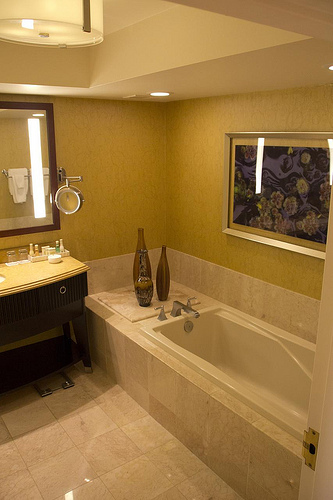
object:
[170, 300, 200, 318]
faucet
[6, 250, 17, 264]
glasses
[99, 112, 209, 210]
wall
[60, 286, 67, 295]
handle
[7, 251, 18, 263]
glass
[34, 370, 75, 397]
scale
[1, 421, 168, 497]
floor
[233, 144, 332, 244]
artwork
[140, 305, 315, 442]
bathtub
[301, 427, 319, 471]
striking plate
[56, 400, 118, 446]
tile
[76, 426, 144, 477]
tile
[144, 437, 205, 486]
tile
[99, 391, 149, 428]
tile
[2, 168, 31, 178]
rack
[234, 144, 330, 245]
flowered print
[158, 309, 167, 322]
faucet handle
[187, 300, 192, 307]
faucet handle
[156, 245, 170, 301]
decorations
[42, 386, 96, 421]
tile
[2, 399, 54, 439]
tile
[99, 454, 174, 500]
tile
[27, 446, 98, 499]
tile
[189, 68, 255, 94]
ceiling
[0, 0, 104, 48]
light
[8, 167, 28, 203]
towel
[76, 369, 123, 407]
tiles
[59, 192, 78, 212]
mirror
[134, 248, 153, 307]
brown vase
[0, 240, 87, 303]
counter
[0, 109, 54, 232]
mirror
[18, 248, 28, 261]
glasses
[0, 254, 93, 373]
counter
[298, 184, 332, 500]
door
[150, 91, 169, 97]
light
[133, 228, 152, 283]
vase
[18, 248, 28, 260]
glass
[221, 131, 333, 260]
border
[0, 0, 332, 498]
bathroom